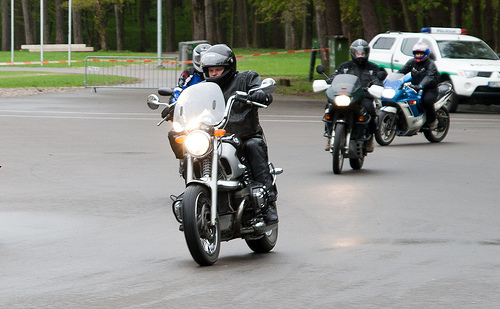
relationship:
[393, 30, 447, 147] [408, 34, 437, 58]
rider has helmet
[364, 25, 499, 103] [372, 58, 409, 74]
police car with stripe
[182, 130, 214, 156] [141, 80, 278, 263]
light on front motorcycle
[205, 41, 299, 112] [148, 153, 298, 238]
rider on motorcyle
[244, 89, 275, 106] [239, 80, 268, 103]
glove on left hand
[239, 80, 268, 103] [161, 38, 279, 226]
left hand on rider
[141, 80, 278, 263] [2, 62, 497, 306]
motorcycle on street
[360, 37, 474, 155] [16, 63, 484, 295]
motorcycle on street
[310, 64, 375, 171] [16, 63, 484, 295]
motorcycle on street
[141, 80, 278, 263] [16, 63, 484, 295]
motorcycle on street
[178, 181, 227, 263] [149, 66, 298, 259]
wheel on motorbike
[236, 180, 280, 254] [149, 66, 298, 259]
wheel on motorbike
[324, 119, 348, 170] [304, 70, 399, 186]
wheel on motorbike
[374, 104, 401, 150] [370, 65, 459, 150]
wheel on motorbike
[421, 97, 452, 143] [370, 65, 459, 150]
wheel on motorbike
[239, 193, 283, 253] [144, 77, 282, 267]
wheel on motorbike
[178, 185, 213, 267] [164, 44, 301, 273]
wheel on motorbike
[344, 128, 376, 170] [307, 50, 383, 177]
wheel on bike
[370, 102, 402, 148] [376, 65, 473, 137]
wheel on motor bike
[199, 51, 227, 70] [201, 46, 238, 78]
visor on helmet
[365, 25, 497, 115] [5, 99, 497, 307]
suv in parking lot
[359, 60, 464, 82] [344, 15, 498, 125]
stripe on suv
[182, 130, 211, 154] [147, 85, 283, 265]
headlight on motorcycle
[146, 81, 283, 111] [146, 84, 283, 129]
mirrors attached to handlebars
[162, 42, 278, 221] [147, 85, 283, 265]
man riding a motorcycle